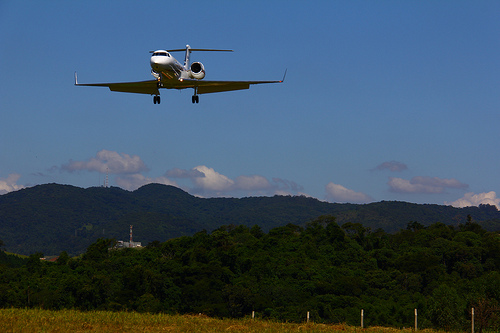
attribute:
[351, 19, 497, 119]
blue skies — blue 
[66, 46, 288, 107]
aircraft — large, flying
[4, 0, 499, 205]
skies — blue 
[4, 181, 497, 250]
mountains — distant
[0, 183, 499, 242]
hills — green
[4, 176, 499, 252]
trees — distant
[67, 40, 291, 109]
plane — grey.